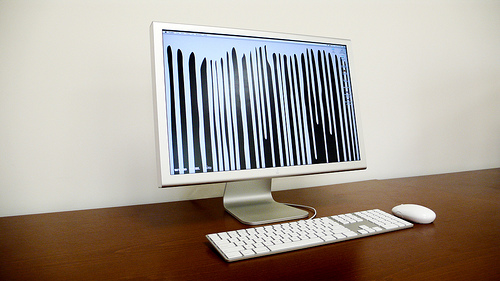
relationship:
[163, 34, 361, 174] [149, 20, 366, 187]
image on screen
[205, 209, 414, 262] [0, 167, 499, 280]
keyboard on table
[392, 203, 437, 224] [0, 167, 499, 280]
mouse on table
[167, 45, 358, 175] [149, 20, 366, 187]
lines in screen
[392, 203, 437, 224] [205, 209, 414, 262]
mouse beside keyboard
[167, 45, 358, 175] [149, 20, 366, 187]
stripes are on monitor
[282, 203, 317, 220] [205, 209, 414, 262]
cord connects keyboard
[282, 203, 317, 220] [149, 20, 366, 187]
cord connects monitor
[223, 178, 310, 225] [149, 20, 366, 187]
support holds screen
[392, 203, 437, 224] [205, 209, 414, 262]
mouse next to keyboard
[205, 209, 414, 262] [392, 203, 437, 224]
keyboard next to mouse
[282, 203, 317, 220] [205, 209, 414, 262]
wire connects keyboard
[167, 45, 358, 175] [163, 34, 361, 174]
lines against background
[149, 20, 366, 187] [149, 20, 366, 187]
frame around screen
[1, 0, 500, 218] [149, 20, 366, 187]
wall behind screen